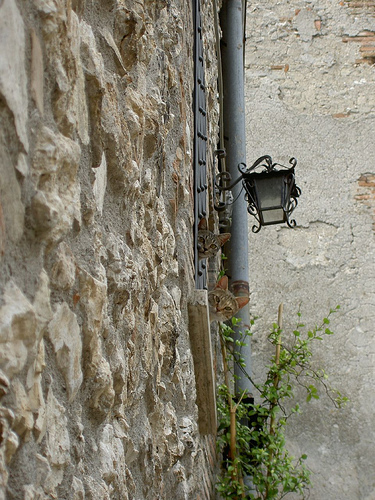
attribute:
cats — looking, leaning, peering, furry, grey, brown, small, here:
[186, 217, 235, 307]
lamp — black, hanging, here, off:
[260, 161, 313, 219]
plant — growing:
[199, 351, 300, 478]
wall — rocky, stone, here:
[271, 12, 366, 73]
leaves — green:
[267, 319, 322, 345]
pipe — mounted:
[247, 128, 250, 131]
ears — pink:
[193, 219, 230, 242]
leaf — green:
[265, 318, 286, 354]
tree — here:
[192, 433, 302, 493]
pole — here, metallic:
[214, 134, 250, 157]